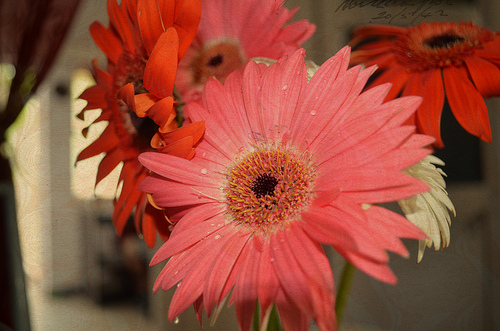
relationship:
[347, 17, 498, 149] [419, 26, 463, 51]
flower on center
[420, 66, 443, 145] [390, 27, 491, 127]
petal on flower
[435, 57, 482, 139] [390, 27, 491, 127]
petal on flower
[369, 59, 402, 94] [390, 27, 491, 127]
petal on flower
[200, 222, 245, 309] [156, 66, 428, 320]
petal on flower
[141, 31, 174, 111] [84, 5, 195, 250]
petal on flower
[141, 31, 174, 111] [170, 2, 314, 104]
petal on flower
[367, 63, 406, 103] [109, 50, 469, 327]
petal on flower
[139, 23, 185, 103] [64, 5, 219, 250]
petals on flower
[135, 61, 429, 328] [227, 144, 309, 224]
flower has center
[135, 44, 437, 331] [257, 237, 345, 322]
flower has petal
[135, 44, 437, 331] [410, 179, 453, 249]
flower has petal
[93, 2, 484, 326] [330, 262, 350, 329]
flower has stem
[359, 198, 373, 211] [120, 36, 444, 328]
specks are on flower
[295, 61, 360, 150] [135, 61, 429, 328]
petal on flower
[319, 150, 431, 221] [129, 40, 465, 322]
petal on flower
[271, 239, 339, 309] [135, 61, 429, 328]
petal on flower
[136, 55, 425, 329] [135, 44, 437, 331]
petal on flower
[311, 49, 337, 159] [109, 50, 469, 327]
petal on flower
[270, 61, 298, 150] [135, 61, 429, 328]
petal on flower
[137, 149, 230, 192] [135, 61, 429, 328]
pink petal on flower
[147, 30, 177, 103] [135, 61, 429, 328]
petal on flower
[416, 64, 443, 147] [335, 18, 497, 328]
petal on flower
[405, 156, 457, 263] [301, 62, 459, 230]
white petals on flower